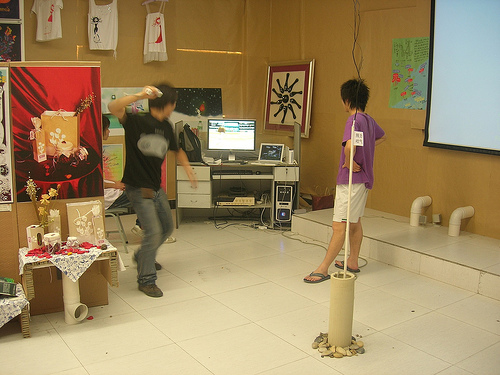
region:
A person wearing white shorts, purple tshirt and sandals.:
[302, 78, 387, 286]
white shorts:
[331, 178, 372, 226]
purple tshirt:
[333, 112, 388, 190]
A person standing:
[298, 77, 387, 280]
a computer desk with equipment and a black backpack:
[172, 119, 299, 233]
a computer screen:
[206, 115, 256, 151]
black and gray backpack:
[175, 122, 208, 166]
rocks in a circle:
[312, 329, 366, 361]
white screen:
[420, 0, 497, 148]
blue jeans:
[118, 182, 174, 284]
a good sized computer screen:
[207, 115, 254, 150]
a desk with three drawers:
[171, 159, 275, 227]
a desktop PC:
[270, 180, 297, 236]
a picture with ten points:
[257, 55, 319, 140]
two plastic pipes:
[388, 188, 488, 243]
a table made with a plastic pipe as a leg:
[17, 227, 120, 328]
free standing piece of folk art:
[310, 121, 367, 360]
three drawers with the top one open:
[173, 160, 213, 212]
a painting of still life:
[8, 60, 103, 201]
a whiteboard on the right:
[422, 0, 497, 156]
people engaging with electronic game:
[92, 60, 389, 320]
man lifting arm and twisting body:
[100, 50, 195, 315]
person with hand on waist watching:
[286, 65, 391, 285]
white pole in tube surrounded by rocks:
[306, 80, 372, 360]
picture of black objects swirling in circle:
[260, 60, 312, 140]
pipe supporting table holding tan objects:
[10, 195, 131, 325]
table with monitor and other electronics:
[165, 95, 300, 237]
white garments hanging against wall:
[30, 0, 190, 70]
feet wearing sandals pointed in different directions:
[255, 210, 375, 295]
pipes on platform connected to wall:
[397, 163, 478, 289]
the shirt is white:
[340, 113, 385, 178]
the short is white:
[327, 185, 379, 225]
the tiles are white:
[205, 288, 257, 370]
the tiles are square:
[205, 272, 302, 329]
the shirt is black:
[115, 111, 185, 189]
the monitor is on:
[211, 115, 278, 157]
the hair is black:
[329, 75, 379, 120]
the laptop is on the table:
[255, 136, 304, 181]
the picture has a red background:
[4, 63, 108, 201]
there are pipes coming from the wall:
[410, 191, 483, 251]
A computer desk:
[175, 115, 305, 220]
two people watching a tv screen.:
[109, 73, 389, 288]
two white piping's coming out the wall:
[405, 189, 477, 239]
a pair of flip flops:
[305, 251, 362, 283]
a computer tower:
[275, 180, 294, 225]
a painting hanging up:
[9, 58, 109, 205]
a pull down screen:
[417, 0, 499, 187]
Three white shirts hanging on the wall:
[27, 1, 187, 70]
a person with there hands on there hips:
[322, 74, 384, 194]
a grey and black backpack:
[173, 120, 207, 160]